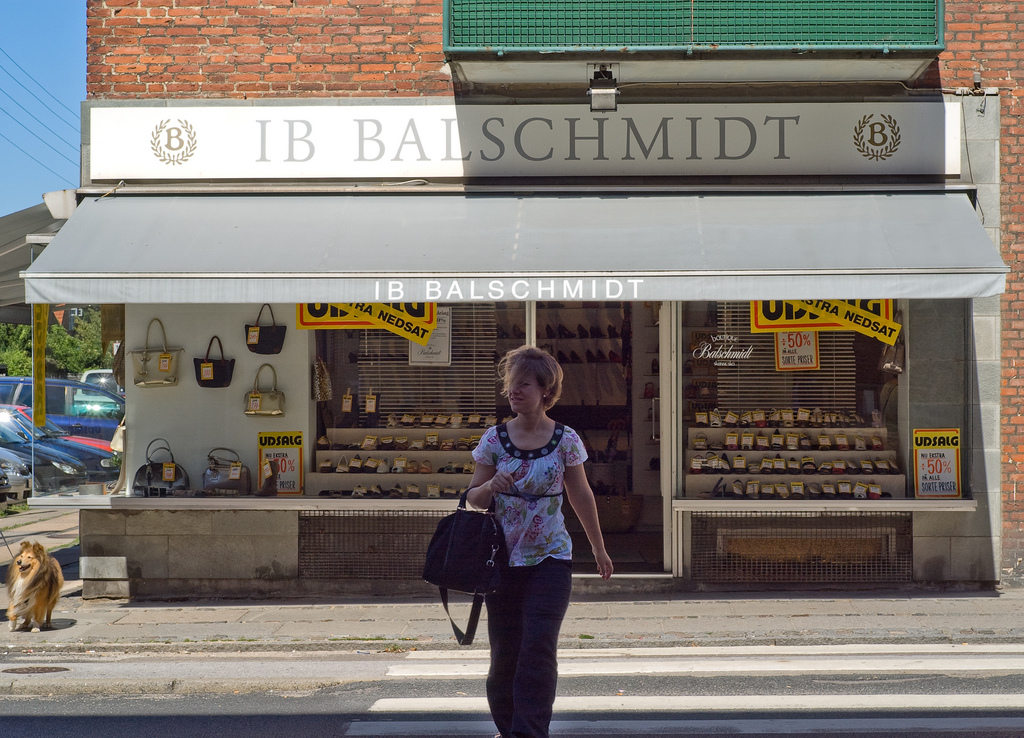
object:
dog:
[0, 532, 71, 638]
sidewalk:
[0, 525, 1023, 734]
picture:
[0, 0, 1024, 738]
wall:
[92, 297, 1006, 615]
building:
[9, 0, 1022, 604]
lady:
[447, 327, 628, 738]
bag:
[414, 479, 511, 650]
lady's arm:
[463, 423, 516, 513]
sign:
[250, 108, 813, 170]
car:
[0, 374, 137, 424]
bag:
[235, 357, 296, 423]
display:
[27, 269, 991, 513]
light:
[574, 55, 633, 121]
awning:
[431, 35, 940, 99]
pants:
[399, 530, 655, 646]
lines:
[348, 676, 1024, 728]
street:
[0, 578, 1024, 737]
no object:
[97, 555, 292, 670]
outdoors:
[0, 0, 1024, 738]